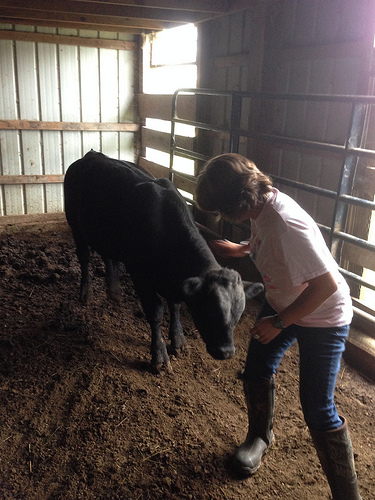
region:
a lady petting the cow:
[58, 114, 364, 394]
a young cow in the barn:
[51, 151, 282, 414]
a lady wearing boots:
[229, 372, 370, 486]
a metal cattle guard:
[177, 80, 374, 254]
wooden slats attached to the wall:
[4, 81, 172, 206]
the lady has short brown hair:
[180, 145, 285, 243]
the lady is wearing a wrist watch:
[255, 300, 302, 353]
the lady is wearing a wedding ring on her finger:
[248, 327, 268, 345]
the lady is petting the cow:
[162, 125, 359, 409]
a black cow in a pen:
[47, 109, 252, 388]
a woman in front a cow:
[50, 126, 369, 489]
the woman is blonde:
[177, 143, 308, 259]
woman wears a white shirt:
[185, 145, 359, 356]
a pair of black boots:
[229, 361, 362, 498]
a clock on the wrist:
[264, 305, 289, 335]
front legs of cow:
[134, 287, 194, 380]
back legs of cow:
[69, 243, 130, 309]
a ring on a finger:
[244, 310, 276, 350]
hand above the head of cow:
[174, 222, 257, 371]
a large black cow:
[62, 148, 265, 373]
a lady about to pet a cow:
[60, 149, 362, 499]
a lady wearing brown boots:
[193, 151, 362, 498]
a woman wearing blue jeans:
[194, 154, 364, 495]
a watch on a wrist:
[269, 312, 287, 332]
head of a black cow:
[183, 266, 264, 360]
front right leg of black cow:
[134, 285, 173, 376]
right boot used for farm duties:
[229, 371, 278, 475]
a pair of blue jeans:
[243, 298, 349, 431]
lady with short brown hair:
[193, 153, 354, 499]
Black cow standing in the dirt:
[63, 148, 264, 373]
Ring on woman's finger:
[253, 333, 259, 339]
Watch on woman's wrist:
[270, 314, 286, 330]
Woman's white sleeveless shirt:
[250, 188, 351, 326]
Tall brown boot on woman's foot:
[231, 377, 276, 477]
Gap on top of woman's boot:
[312, 414, 347, 434]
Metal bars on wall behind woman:
[169, 88, 372, 323]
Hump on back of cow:
[133, 178, 176, 195]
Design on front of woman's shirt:
[249, 233, 277, 295]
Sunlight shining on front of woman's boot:
[232, 429, 268, 475]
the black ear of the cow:
[182, 274, 200, 292]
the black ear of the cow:
[244, 279, 263, 294]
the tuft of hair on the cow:
[212, 266, 237, 281]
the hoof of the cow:
[150, 360, 174, 374]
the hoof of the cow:
[173, 339, 187, 353]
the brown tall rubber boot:
[231, 370, 279, 473]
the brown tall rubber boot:
[306, 412, 359, 497]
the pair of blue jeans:
[247, 306, 336, 418]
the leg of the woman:
[243, 299, 293, 375]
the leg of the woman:
[297, 320, 340, 428]